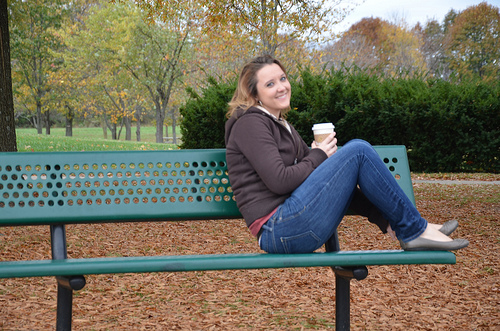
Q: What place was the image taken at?
A: It was taken at the park.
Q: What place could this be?
A: It is a park.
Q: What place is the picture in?
A: It is at the park.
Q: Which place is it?
A: It is a park.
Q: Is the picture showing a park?
A: Yes, it is showing a park.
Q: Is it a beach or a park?
A: It is a park.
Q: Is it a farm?
A: No, it is a park.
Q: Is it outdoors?
A: Yes, it is outdoors.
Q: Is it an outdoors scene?
A: Yes, it is outdoors.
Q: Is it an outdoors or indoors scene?
A: It is outdoors.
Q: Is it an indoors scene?
A: No, it is outdoors.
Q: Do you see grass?
A: Yes, there is grass.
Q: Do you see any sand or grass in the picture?
A: Yes, there is grass.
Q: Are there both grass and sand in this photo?
A: No, there is grass but no sand.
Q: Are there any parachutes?
A: No, there are no parachutes.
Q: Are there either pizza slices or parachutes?
A: No, there are no parachutes or pizza slices.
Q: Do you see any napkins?
A: No, there are no napkins.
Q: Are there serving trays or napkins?
A: No, there are no napkins or serving trays.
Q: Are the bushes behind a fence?
A: No, the bushes are behind the woman.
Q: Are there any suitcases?
A: No, there are no suitcases.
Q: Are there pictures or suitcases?
A: No, there are no suitcases or pictures.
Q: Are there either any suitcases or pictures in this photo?
A: No, there are no suitcases or pictures.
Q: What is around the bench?
A: The leaves are around the bench.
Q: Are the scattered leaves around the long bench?
A: Yes, the leaves are around the bench.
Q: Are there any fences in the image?
A: No, there are no fences.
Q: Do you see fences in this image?
A: No, there are no fences.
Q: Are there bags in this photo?
A: No, there are no bags.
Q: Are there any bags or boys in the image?
A: No, there are no bags or boys.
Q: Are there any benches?
A: Yes, there is a bench.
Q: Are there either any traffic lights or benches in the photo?
A: Yes, there is a bench.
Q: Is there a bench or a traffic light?
A: Yes, there is a bench.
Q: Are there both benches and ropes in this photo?
A: No, there is a bench but no ropes.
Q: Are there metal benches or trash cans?
A: Yes, there is a metal bench.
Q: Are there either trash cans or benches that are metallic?
A: Yes, the bench is metallic.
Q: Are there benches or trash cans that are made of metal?
A: Yes, the bench is made of metal.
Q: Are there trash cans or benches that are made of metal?
A: Yes, the bench is made of metal.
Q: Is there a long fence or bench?
A: Yes, there is a long bench.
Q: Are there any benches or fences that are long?
A: Yes, the bench is long.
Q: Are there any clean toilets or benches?
A: Yes, there is a clean bench.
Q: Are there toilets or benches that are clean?
A: Yes, the bench is clean.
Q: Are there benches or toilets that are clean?
A: Yes, the bench is clean.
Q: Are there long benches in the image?
A: Yes, there is a long bench.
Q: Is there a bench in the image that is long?
A: Yes, there is a bench that is long.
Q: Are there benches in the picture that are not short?
A: Yes, there is a long bench.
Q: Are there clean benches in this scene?
A: Yes, there is a clean bench.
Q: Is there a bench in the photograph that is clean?
A: Yes, there is a bench that is clean.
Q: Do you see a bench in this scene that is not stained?
A: Yes, there is a clean bench.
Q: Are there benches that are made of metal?
A: Yes, there is a bench that is made of metal.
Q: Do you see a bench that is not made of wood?
A: Yes, there is a bench that is made of metal.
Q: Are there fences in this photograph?
A: No, there are no fences.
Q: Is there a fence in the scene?
A: No, there are no fences.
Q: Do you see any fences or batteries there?
A: No, there are no fences or batteries.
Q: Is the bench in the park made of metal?
A: Yes, the bench is made of metal.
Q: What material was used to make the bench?
A: The bench is made of metal.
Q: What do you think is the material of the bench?
A: The bench is made of metal.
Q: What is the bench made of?
A: The bench is made of metal.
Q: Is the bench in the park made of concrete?
A: No, the bench is made of metal.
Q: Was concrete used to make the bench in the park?
A: No, the bench is made of metal.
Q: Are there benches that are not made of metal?
A: No, there is a bench but it is made of metal.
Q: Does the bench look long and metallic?
A: Yes, the bench is long and metallic.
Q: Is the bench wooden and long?
A: No, the bench is long but metallic.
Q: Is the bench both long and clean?
A: Yes, the bench is long and clean.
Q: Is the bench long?
A: Yes, the bench is long.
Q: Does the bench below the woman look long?
A: Yes, the bench is long.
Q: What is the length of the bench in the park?
A: The bench is long.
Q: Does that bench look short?
A: No, the bench is long.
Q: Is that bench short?
A: No, the bench is long.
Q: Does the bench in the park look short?
A: No, the bench is long.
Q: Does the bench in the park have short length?
A: No, the bench is long.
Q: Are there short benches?
A: No, there is a bench but it is long.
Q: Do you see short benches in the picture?
A: No, there is a bench but it is long.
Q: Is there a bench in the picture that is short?
A: No, there is a bench but it is long.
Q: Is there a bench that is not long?
A: No, there is a bench but it is long.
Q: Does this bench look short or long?
A: The bench is long.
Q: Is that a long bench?
A: Yes, that is a long bench.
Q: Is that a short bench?
A: No, that is a long bench.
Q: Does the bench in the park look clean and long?
A: Yes, the bench is clean and long.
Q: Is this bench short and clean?
A: No, the bench is clean but long.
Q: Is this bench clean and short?
A: No, the bench is clean but long.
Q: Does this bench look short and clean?
A: No, the bench is clean but long.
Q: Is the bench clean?
A: Yes, the bench is clean.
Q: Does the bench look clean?
A: Yes, the bench is clean.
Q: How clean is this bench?
A: The bench is clean.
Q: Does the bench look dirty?
A: No, the bench is clean.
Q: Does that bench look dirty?
A: No, the bench is clean.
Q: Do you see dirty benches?
A: No, there is a bench but it is clean.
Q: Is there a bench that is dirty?
A: No, there is a bench but it is clean.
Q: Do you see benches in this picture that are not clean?
A: No, there is a bench but it is clean.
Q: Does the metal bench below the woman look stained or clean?
A: The bench is clean.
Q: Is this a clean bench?
A: Yes, this is a clean bench.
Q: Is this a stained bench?
A: No, this is a clean bench.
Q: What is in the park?
A: The bench is in the park.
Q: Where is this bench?
A: The bench is in the park.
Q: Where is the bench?
A: The bench is in the park.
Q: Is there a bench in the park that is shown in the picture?
A: Yes, there is a bench in the park.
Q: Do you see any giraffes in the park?
A: No, there is a bench in the park.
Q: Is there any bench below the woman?
A: Yes, there is a bench below the woman.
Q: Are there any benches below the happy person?
A: Yes, there is a bench below the woman.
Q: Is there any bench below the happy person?
A: Yes, there is a bench below the woman.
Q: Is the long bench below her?
A: Yes, the bench is below the woman.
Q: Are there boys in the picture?
A: No, there are no boys.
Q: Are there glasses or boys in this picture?
A: No, there are no boys or glasses.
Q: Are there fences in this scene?
A: No, there are no fences.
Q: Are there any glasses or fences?
A: No, there are no fences or glasses.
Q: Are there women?
A: Yes, there is a woman.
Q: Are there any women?
A: Yes, there is a woman.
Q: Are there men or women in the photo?
A: Yes, there is a woman.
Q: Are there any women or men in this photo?
A: Yes, there is a woman.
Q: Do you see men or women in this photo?
A: Yes, there is a woman.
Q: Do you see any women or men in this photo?
A: Yes, there is a woman.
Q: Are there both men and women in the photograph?
A: No, there is a woman but no men.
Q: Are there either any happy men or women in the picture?
A: Yes, there is a happy woman.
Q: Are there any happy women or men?
A: Yes, there is a happy woman.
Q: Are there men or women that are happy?
A: Yes, the woman is happy.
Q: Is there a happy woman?
A: Yes, there is a happy woman.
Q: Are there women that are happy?
A: Yes, there is a woman that is happy.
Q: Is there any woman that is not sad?
A: Yes, there is a happy woman.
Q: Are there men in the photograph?
A: No, there are no men.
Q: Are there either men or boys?
A: No, there are no men or boys.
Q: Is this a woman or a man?
A: This is a woman.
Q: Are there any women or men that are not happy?
A: No, there is a woman but she is happy.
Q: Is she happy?
A: Yes, the woman is happy.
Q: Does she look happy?
A: Yes, the woman is happy.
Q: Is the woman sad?
A: No, the woman is happy.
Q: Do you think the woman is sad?
A: No, the woman is happy.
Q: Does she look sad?
A: No, the woman is happy.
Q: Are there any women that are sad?
A: No, there is a woman but she is happy.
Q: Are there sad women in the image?
A: No, there is a woman but she is happy.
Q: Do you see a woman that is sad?
A: No, there is a woman but she is happy.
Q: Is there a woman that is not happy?
A: No, there is a woman but she is happy.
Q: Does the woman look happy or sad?
A: The woman is happy.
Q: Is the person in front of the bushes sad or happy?
A: The woman is happy.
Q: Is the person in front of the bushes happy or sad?
A: The woman is happy.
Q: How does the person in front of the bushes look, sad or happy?
A: The woman is happy.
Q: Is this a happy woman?
A: Yes, this is a happy woman.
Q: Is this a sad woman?
A: No, this is a happy woman.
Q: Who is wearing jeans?
A: The woman is wearing jeans.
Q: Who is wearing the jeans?
A: The woman is wearing jeans.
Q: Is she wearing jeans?
A: Yes, the woman is wearing jeans.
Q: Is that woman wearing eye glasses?
A: No, the woman is wearing jeans.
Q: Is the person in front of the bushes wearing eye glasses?
A: No, the woman is wearing jeans.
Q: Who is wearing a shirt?
A: The woman is wearing a shirt.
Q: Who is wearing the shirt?
A: The woman is wearing a shirt.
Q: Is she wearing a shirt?
A: Yes, the woman is wearing a shirt.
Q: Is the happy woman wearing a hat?
A: No, the woman is wearing a shirt.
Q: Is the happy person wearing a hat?
A: No, the woman is wearing a shirt.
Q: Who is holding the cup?
A: The woman is holding the cup.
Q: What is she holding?
A: The woman is holding the cup.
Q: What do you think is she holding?
A: The woman is holding the cup.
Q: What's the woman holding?
A: The woman is holding the cup.